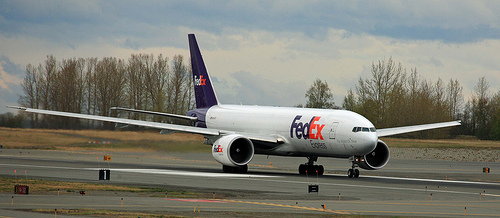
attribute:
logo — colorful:
[286, 112, 331, 143]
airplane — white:
[103, 30, 473, 200]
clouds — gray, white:
[260, 27, 317, 63]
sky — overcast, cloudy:
[118, 15, 393, 79]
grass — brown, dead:
[28, 129, 87, 151]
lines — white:
[133, 160, 281, 187]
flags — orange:
[100, 152, 114, 162]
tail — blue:
[182, 37, 223, 119]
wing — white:
[26, 90, 222, 146]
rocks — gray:
[420, 145, 488, 164]